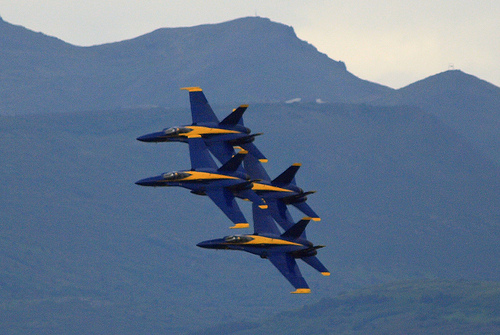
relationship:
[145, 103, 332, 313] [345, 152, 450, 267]
planes in air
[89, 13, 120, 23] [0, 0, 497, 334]
clouds in sky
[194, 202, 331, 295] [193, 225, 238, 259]
airplane has front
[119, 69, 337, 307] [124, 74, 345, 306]
planes in formation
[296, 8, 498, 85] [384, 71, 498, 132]
sky above mountain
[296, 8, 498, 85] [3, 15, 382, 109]
sky above mountain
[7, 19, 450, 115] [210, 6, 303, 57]
hill has top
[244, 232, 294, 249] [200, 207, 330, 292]
strip in plane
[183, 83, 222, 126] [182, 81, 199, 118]
wing has edge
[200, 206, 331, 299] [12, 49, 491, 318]
airplane in air